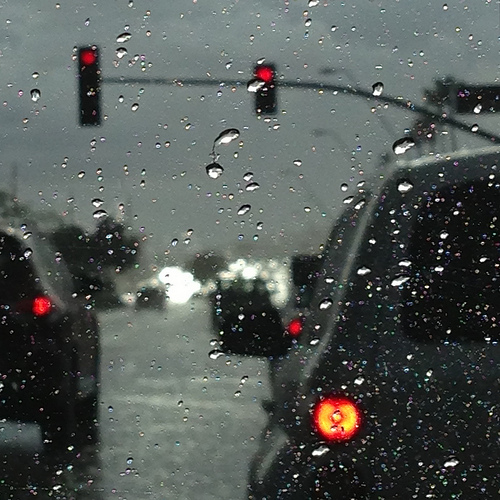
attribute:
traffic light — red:
[249, 58, 282, 121]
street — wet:
[102, 325, 252, 488]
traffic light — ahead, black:
[76, 45, 103, 130]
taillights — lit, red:
[307, 385, 364, 451]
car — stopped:
[259, 167, 491, 500]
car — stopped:
[207, 275, 280, 338]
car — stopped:
[2, 223, 101, 461]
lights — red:
[30, 294, 55, 318]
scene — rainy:
[6, 3, 498, 483]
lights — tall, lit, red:
[71, 40, 288, 127]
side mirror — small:
[221, 309, 286, 358]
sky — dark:
[221, 5, 392, 60]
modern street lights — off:
[308, 118, 369, 193]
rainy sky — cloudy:
[151, 98, 254, 199]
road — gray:
[134, 363, 249, 477]